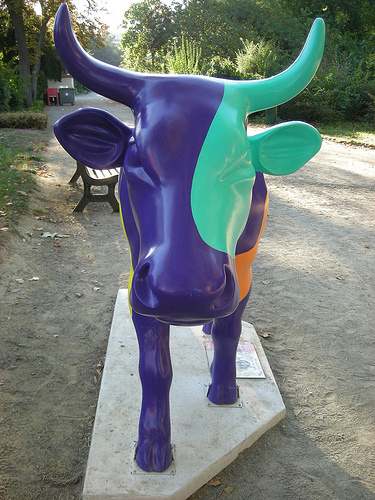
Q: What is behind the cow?
A: A bench.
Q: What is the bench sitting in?
A: Dirt.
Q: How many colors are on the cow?
A: 4.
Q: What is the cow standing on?
A: Concrete.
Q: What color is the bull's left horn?
A: Aqua.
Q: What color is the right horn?
A: Blue.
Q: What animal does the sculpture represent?
A: A bull.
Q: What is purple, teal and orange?
A: The bull.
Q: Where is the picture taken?
A: Park.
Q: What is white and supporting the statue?
A: A base.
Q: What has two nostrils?
A: The nose of the bull.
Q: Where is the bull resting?
A: A brown dirt path.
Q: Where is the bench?
A: Behind the cow.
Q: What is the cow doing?
A: Standing.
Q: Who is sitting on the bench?
A: No man or woman.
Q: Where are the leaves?
A: On the ground.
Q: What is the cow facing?
A: The camera.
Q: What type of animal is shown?
A: Cow.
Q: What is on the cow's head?
A: Horns.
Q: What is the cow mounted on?
A: Concrete slab.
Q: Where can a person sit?
A: Bench.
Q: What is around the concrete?
A: Dirt.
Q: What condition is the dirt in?
A: Dry.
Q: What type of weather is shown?
A: Sunny.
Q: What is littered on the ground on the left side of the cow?
A: Leaves.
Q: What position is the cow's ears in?
A: Out.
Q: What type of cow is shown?
A: Cow statue.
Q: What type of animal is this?
A: A cow.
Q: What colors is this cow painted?
A: Purple, turquoise, and yellow.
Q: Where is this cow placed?
A: In a park.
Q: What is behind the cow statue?
A: A park bench.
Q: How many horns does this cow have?
A: Two.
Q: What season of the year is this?
A: Summer.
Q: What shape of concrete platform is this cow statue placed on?
A: A trapezoid.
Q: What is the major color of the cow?
A: Purple.